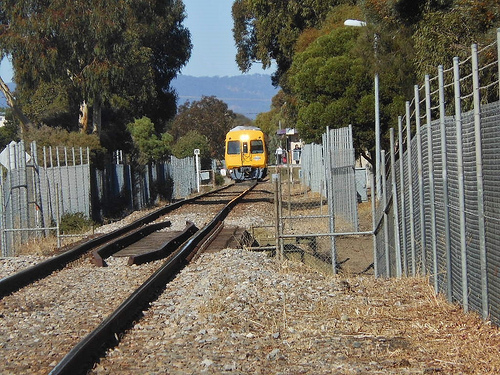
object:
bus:
[217, 119, 270, 183]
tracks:
[0, 176, 251, 374]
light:
[339, 14, 389, 276]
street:
[3, 176, 496, 374]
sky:
[178, 1, 277, 74]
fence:
[298, 42, 499, 320]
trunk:
[73, 94, 106, 153]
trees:
[0, 1, 197, 143]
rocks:
[3, 202, 387, 372]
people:
[274, 141, 304, 164]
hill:
[174, 73, 277, 126]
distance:
[167, 68, 283, 90]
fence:
[0, 141, 207, 197]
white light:
[236, 130, 256, 144]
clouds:
[191, 1, 234, 80]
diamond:
[3, 138, 33, 173]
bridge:
[52, 213, 261, 264]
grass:
[348, 276, 500, 374]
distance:
[257, 108, 328, 164]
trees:
[230, 0, 495, 120]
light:
[238, 132, 251, 144]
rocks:
[190, 244, 420, 370]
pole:
[371, 70, 382, 279]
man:
[273, 143, 285, 164]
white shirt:
[274, 146, 285, 155]